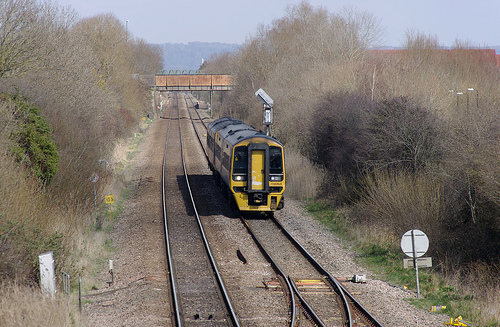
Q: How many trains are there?
A: One.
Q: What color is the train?
A: Yellow.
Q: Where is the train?
A: On the tracks.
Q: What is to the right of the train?
A: A sign.